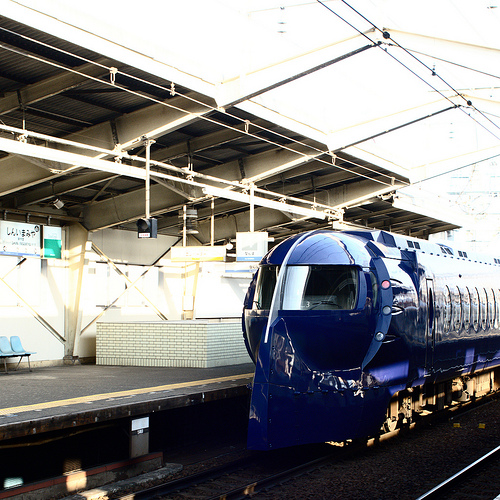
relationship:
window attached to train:
[280, 263, 358, 312] [234, 221, 497, 457]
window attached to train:
[280, 263, 358, 312] [240, 218, 498, 475]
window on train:
[280, 263, 358, 312] [234, 221, 497, 457]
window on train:
[236, 260, 278, 318] [234, 221, 497, 457]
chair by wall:
[8, 331, 34, 368] [3, 261, 64, 367]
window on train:
[252, 260, 279, 310] [242, 221, 499, 456]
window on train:
[280, 263, 358, 312] [242, 221, 499, 456]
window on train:
[444, 284, 454, 331] [242, 221, 499, 456]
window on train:
[470, 283, 482, 333] [242, 221, 499, 456]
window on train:
[424, 289, 438, 333] [242, 221, 499, 456]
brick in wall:
[193, 336, 207, 343] [91, 319, 205, 369]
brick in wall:
[191, 357, 198, 368] [85, 316, 202, 369]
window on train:
[411, 236, 424, 254] [242, 221, 499, 456]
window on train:
[252, 260, 279, 310] [234, 221, 497, 457]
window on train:
[440, 286, 453, 326] [234, 221, 497, 457]